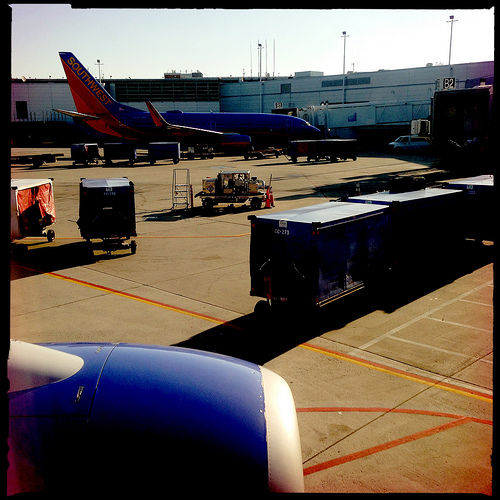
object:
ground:
[14, 145, 499, 497]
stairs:
[173, 200, 185, 203]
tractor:
[198, 170, 276, 210]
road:
[11, 139, 500, 495]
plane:
[55, 50, 323, 159]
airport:
[0, 63, 491, 495]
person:
[265, 186, 273, 199]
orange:
[247, 183, 260, 192]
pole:
[341, 34, 347, 104]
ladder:
[170, 168, 194, 215]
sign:
[277, 219, 286, 225]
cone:
[267, 196, 273, 207]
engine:
[229, 134, 251, 146]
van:
[391, 134, 431, 156]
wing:
[144, 97, 221, 139]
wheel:
[186, 149, 196, 160]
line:
[293, 406, 495, 425]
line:
[362, 278, 491, 350]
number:
[75, 386, 85, 398]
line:
[47, 269, 230, 323]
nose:
[297, 117, 321, 137]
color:
[140, 345, 202, 401]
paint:
[359, 280, 492, 350]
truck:
[78, 177, 138, 257]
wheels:
[91, 244, 99, 256]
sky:
[10, 7, 494, 80]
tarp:
[11, 178, 57, 236]